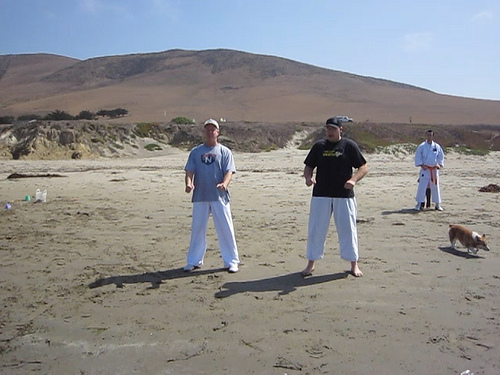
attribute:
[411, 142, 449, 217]
outfit — white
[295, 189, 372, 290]
pants — WHITE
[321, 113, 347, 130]
cap — black, baseball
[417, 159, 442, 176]
belt — ORANGE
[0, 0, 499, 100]
sky — BRIGHT BLUE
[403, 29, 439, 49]
cloud — SMALL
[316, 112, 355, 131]
cap — BLAKE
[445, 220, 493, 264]
dog — brown, white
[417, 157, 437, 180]
belt — RED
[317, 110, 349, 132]
hat — black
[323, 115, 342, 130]
hat — black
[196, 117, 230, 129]
hat — white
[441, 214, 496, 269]
dog — short , brown , white 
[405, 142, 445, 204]
outfit — karate outfit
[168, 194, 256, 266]
pant — white, gii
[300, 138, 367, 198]
black shirt — tee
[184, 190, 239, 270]
pants — WHITE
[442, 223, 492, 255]
dog — WHITE, BROWN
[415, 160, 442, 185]
belt — red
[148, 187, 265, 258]
pants — white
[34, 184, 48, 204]
bucket — white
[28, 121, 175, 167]
dunes — BIG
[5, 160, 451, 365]
shore — sandy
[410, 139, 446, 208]
uniform — karate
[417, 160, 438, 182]
belt — orange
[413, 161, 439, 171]
waist — mans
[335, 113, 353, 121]
truck — white